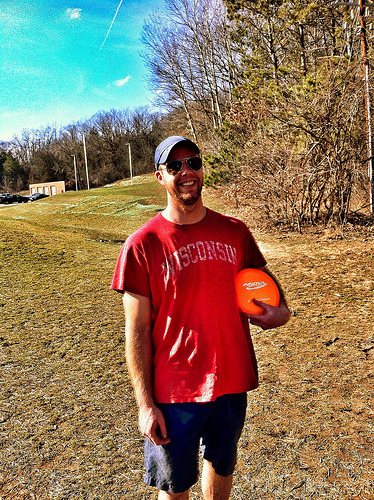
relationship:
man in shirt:
[106, 126, 286, 497] [112, 200, 276, 401]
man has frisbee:
[106, 126, 286, 497] [223, 261, 297, 322]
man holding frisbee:
[106, 126, 286, 497] [223, 261, 297, 322]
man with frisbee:
[106, 126, 286, 497] [223, 261, 297, 322]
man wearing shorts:
[106, 126, 286, 497] [139, 386, 245, 494]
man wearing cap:
[106, 126, 286, 497] [151, 126, 201, 166]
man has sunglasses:
[106, 126, 286, 497] [154, 157, 208, 175]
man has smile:
[106, 126, 286, 497] [172, 175, 207, 194]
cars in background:
[0, 190, 50, 206] [1, 44, 159, 208]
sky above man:
[2, 2, 191, 125] [106, 126, 286, 497]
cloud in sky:
[107, 68, 140, 92] [2, 2, 191, 125]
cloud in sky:
[60, 5, 92, 35] [2, 2, 191, 125]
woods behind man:
[210, 2, 373, 207] [106, 126, 286, 497]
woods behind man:
[0, 112, 163, 188] [106, 126, 286, 497]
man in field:
[106, 126, 286, 497] [25, 190, 159, 376]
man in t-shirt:
[106, 126, 286, 497] [112, 200, 276, 401]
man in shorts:
[106, 126, 286, 497] [139, 386, 245, 494]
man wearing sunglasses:
[106, 126, 286, 497] [154, 157, 208, 175]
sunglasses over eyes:
[154, 157, 208, 175] [163, 157, 204, 176]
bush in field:
[269, 68, 367, 224] [25, 190, 159, 376]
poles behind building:
[65, 126, 136, 190] [20, 149, 70, 204]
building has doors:
[20, 149, 70, 204] [32, 186, 57, 196]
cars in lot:
[0, 190, 50, 206] [1, 196, 37, 217]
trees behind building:
[0, 112, 163, 188] [20, 149, 70, 204]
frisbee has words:
[223, 261, 297, 322] [239, 278, 266, 291]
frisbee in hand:
[223, 261, 297, 322] [245, 296, 303, 335]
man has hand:
[106, 126, 286, 497] [245, 296, 303, 335]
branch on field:
[282, 460, 312, 494] [0, 170, 374, 499]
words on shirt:
[159, 234, 241, 285] [112, 200, 276, 401]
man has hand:
[106, 126, 286, 497] [132, 395, 177, 450]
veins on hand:
[142, 405, 154, 434] [132, 395, 177, 450]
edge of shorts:
[143, 463, 240, 495] [139, 386, 245, 494]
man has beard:
[106, 126, 286, 497] [170, 179, 205, 206]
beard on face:
[170, 179, 205, 206] [162, 154, 211, 212]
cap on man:
[151, 126, 201, 166] [106, 126, 286, 497]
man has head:
[106, 126, 286, 497] [156, 141, 203, 200]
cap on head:
[151, 126, 201, 166] [156, 141, 203, 200]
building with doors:
[20, 149, 70, 204] [32, 186, 57, 196]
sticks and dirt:
[268, 391, 365, 490] [270, 385, 365, 486]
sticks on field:
[268, 391, 365, 490] [0, 170, 374, 499]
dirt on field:
[270, 385, 365, 486] [0, 170, 374, 499]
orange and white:
[256, 291, 277, 299] [244, 279, 260, 291]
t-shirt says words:
[112, 200, 276, 401] [161, 239, 238, 291]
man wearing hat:
[106, 126, 286, 497] [151, 126, 201, 166]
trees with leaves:
[210, 2, 373, 207] [244, 4, 339, 31]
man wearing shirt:
[106, 126, 286, 497] [112, 200, 276, 401]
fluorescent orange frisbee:
[239, 271, 266, 283] [223, 261, 297, 322]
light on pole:
[65, 131, 133, 161] [65, 126, 136, 190]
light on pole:
[65, 131, 133, 161] [64, 147, 83, 196]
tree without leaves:
[171, 4, 279, 158] [244, 4, 339, 31]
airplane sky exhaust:
[95, 43, 108, 54] [100, 2, 134, 52]